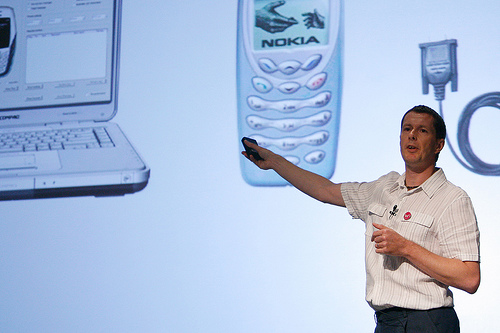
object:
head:
[395, 104, 444, 173]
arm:
[263, 147, 368, 208]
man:
[244, 99, 487, 330]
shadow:
[380, 253, 410, 271]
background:
[1, 1, 483, 329]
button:
[251, 74, 271, 93]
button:
[246, 93, 270, 112]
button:
[275, 80, 300, 94]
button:
[306, 110, 332, 126]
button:
[303, 129, 330, 147]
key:
[50, 140, 62, 146]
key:
[23, 146, 38, 152]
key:
[25, 136, 39, 142]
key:
[66, 127, 81, 133]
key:
[2, 137, 16, 144]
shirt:
[338, 164, 481, 310]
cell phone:
[232, 0, 345, 190]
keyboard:
[2, 123, 116, 153]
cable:
[435, 89, 500, 179]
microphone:
[386, 203, 398, 221]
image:
[2, 1, 483, 330]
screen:
[252, 1, 332, 49]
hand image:
[254, 1, 298, 32]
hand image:
[298, 7, 326, 30]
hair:
[402, 103, 449, 111]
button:
[402, 210, 411, 218]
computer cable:
[416, 38, 483, 178]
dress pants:
[372, 301, 462, 331]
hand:
[240, 137, 273, 172]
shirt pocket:
[364, 200, 391, 240]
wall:
[56, 205, 316, 332]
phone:
[239, 135, 263, 163]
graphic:
[0, 0, 157, 209]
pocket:
[400, 211, 432, 241]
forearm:
[355, 179, 481, 296]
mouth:
[400, 140, 420, 154]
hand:
[369, 222, 405, 257]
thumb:
[370, 222, 389, 231]